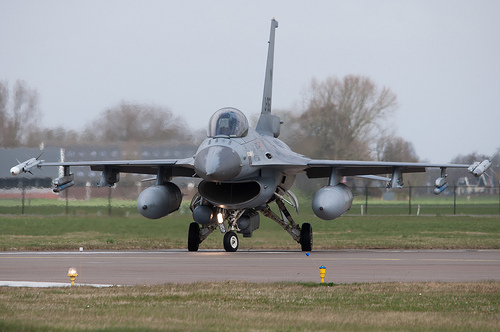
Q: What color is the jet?
A: Grey.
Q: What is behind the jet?
A: A fence.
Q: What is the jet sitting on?
A: The runway.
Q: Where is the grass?
A: By the fence.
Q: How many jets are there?
A: One.